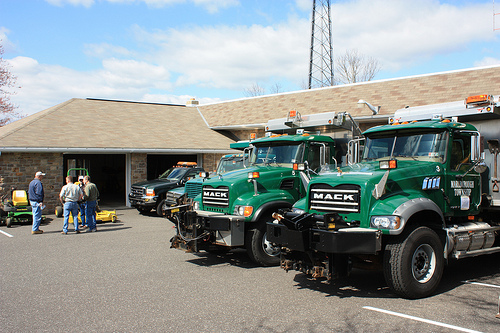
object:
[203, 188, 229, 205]
mack emblem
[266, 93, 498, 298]
truck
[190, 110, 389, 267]
leg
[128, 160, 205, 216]
leg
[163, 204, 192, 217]
leg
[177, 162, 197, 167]
light bar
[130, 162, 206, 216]
truck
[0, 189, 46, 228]
equipment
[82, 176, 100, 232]
man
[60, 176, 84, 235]
man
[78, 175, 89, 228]
man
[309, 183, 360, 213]
emblem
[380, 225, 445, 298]
black tire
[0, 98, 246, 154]
roof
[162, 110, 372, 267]
green truck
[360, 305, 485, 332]
line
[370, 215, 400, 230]
lights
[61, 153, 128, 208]
door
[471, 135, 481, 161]
mirror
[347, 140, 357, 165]
mirror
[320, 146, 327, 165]
mirror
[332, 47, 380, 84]
tree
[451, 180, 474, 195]
white print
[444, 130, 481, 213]
door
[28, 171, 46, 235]
man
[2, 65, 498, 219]
building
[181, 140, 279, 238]
truck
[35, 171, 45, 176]
cap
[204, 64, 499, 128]
roof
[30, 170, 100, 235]
group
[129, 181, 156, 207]
front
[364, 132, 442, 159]
windshield